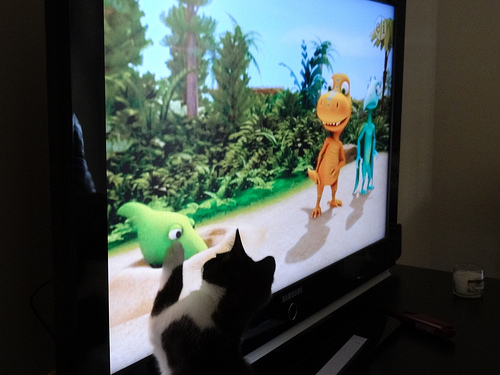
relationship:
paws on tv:
[163, 243, 185, 269] [65, 7, 406, 302]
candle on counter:
[449, 259, 489, 303] [416, 277, 434, 298]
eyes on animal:
[327, 86, 347, 94] [306, 65, 355, 223]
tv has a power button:
[65, 7, 406, 302] [285, 301, 303, 323]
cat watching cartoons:
[145, 226, 278, 373] [106, 64, 397, 253]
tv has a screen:
[65, 7, 406, 302] [140, 37, 303, 148]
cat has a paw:
[145, 226, 278, 373] [163, 243, 185, 269]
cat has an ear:
[145, 226, 278, 373] [225, 225, 249, 252]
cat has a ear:
[145, 226, 278, 373] [225, 225, 249, 252]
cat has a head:
[145, 226, 278, 373] [203, 224, 279, 300]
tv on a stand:
[65, 7, 406, 302] [344, 297, 384, 322]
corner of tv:
[392, 247, 403, 280] [65, 7, 406, 302]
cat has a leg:
[145, 226, 278, 373] [155, 269, 183, 302]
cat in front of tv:
[145, 226, 278, 373] [65, 7, 406, 302]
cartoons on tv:
[106, 64, 397, 253] [65, 7, 406, 302]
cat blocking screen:
[145, 226, 278, 373] [100, 0, 397, 375]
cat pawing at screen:
[145, 226, 278, 373] [140, 37, 303, 148]